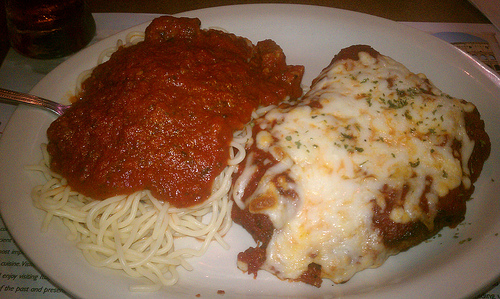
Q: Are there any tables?
A: Yes, there is a table.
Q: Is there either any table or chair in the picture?
A: Yes, there is a table.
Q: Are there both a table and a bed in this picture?
A: No, there is a table but no beds.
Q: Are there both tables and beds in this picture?
A: No, there is a table but no beds.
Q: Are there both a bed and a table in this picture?
A: No, there is a table but no beds.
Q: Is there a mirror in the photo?
A: No, there are no mirrors.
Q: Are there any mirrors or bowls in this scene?
A: No, there are no mirrors or bowls.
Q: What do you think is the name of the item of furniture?
A: The piece of furniture is a table.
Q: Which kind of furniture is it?
A: The piece of furniture is a table.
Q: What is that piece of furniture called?
A: This is a table.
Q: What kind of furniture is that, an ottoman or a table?
A: This is a table.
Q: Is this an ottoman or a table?
A: This is a table.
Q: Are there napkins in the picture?
A: No, there are no napkins.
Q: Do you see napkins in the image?
A: No, there are no napkins.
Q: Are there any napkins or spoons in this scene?
A: No, there are no napkins or spoons.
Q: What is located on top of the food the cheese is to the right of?
A: The sauce is on top of the noodles.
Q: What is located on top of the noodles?
A: The sauce is on top of the noodles.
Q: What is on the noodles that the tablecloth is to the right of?
A: The sauce is on the noodles.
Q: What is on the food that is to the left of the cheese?
A: The sauce is on the noodles.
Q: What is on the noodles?
A: The sauce is on the noodles.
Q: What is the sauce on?
A: The sauce is on the noodles.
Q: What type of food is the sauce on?
A: The sauce is on the noodles.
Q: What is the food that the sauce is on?
A: The food is noodles.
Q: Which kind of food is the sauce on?
A: The sauce is on the noodles.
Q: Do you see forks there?
A: Yes, there is a fork.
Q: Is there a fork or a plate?
A: Yes, there is a fork.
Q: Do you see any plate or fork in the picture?
A: Yes, there is a fork.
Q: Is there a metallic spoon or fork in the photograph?
A: Yes, there is a metal fork.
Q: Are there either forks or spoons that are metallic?
A: Yes, the fork is metallic.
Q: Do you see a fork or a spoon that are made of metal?
A: Yes, the fork is made of metal.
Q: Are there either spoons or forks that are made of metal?
A: Yes, the fork is made of metal.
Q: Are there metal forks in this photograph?
A: Yes, there is a metal fork.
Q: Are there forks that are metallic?
A: Yes, there is a fork that is metallic.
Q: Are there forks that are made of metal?
A: Yes, there is a fork that is made of metal.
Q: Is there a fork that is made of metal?
A: Yes, there is a fork that is made of metal.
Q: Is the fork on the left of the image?
A: Yes, the fork is on the left of the image.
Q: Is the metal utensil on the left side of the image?
A: Yes, the fork is on the left of the image.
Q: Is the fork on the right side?
A: No, the fork is on the left of the image.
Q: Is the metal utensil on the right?
A: No, the fork is on the left of the image.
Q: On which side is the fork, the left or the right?
A: The fork is on the left of the image.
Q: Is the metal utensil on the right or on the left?
A: The fork is on the left of the image.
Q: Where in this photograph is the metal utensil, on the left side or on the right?
A: The fork is on the left of the image.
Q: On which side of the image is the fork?
A: The fork is on the left of the image.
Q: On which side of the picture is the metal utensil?
A: The fork is on the left of the image.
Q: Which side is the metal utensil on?
A: The fork is on the left of the image.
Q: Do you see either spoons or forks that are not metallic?
A: No, there is a fork but it is metallic.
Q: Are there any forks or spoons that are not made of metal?
A: No, there is a fork but it is made of metal.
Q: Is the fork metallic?
A: Yes, the fork is metallic.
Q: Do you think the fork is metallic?
A: Yes, the fork is metallic.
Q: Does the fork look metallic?
A: Yes, the fork is metallic.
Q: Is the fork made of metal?
A: Yes, the fork is made of metal.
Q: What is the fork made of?
A: The fork is made of metal.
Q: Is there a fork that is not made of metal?
A: No, there is a fork but it is made of metal.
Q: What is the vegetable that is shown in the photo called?
A: The vegetable is a herb.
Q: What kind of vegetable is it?
A: The vegetable is a herb.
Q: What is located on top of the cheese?
A: The herb is on top of the cheese.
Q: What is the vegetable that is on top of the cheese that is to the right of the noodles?
A: The vegetable is a herb.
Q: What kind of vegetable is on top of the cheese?
A: The vegetable is a herb.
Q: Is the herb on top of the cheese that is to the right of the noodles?
A: Yes, the herb is on top of the cheese.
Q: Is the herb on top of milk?
A: No, the herb is on top of the cheese.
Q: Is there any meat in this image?
A: Yes, there is meat.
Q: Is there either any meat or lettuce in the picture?
A: Yes, there is meat.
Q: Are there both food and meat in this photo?
A: Yes, there are both meat and food.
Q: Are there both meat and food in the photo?
A: Yes, there are both meat and food.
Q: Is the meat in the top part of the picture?
A: Yes, the meat is in the top of the image.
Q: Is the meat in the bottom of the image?
A: No, the meat is in the top of the image.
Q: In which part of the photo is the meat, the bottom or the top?
A: The meat is in the top of the image.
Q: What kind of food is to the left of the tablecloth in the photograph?
A: The food is meat.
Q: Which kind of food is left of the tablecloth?
A: The food is meat.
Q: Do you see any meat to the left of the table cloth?
A: Yes, there is meat to the left of the table cloth.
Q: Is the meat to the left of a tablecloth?
A: Yes, the meat is to the left of a tablecloth.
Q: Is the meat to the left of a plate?
A: No, the meat is to the left of a tablecloth.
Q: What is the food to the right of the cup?
A: The food is meat.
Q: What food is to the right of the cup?
A: The food is meat.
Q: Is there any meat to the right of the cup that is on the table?
A: Yes, there is meat to the right of the cup.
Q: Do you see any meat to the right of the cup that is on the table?
A: Yes, there is meat to the right of the cup.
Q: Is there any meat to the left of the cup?
A: No, the meat is to the right of the cup.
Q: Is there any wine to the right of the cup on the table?
A: No, there is meat to the right of the cup.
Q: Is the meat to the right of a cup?
A: Yes, the meat is to the right of a cup.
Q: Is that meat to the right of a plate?
A: No, the meat is to the right of a cup.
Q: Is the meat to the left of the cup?
A: No, the meat is to the right of the cup.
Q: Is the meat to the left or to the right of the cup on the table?
A: The meat is to the right of the cup.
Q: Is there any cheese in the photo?
A: Yes, there is cheese.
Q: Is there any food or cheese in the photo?
A: Yes, there is cheese.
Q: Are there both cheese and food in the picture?
A: Yes, there are both cheese and food.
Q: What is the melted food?
A: The food is cheese.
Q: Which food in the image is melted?
A: The food is cheese.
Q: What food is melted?
A: The food is cheese.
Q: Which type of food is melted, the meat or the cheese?
A: The cheese is melted.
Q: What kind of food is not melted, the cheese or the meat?
A: The meat is not melted.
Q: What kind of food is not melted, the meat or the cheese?
A: The meat is not melted.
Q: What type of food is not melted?
A: The food is meat.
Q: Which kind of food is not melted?
A: The food is meat.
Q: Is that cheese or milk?
A: That is cheese.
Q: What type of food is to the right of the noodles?
A: The food is cheese.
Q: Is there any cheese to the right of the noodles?
A: Yes, there is cheese to the right of the noodles.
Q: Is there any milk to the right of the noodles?
A: No, there is cheese to the right of the noodles.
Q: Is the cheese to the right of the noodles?
A: Yes, the cheese is to the right of the noodles.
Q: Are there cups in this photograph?
A: Yes, there is a cup.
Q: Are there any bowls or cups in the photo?
A: Yes, there is a cup.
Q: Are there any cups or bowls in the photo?
A: Yes, there is a cup.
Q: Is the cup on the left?
A: Yes, the cup is on the left of the image.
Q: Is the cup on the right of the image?
A: No, the cup is on the left of the image.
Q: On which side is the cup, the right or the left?
A: The cup is on the left of the image.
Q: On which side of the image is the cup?
A: The cup is on the left of the image.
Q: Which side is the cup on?
A: The cup is on the left of the image.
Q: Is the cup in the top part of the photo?
A: Yes, the cup is in the top of the image.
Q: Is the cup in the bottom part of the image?
A: No, the cup is in the top of the image.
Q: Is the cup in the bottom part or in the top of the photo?
A: The cup is in the top of the image.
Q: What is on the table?
A: The cup is on the table.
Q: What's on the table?
A: The cup is on the table.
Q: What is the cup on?
A: The cup is on the table.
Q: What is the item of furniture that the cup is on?
A: The piece of furniture is a table.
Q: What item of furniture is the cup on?
A: The cup is on the table.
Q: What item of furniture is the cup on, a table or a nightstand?
A: The cup is on a table.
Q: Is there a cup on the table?
A: Yes, there is a cup on the table.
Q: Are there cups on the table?
A: Yes, there is a cup on the table.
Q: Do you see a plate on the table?
A: No, there is a cup on the table.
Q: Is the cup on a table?
A: Yes, the cup is on a table.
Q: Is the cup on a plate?
A: No, the cup is on a table.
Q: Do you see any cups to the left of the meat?
A: Yes, there is a cup to the left of the meat.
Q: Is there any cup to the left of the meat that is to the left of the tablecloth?
A: Yes, there is a cup to the left of the meat.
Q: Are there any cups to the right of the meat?
A: No, the cup is to the left of the meat.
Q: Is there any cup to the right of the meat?
A: No, the cup is to the left of the meat.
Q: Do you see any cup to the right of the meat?
A: No, the cup is to the left of the meat.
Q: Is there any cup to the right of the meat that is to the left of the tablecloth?
A: No, the cup is to the left of the meat.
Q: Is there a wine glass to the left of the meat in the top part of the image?
A: No, there is a cup to the left of the meat.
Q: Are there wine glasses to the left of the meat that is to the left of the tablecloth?
A: No, there is a cup to the left of the meat.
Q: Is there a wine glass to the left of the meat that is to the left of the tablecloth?
A: No, there is a cup to the left of the meat.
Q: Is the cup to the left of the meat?
A: Yes, the cup is to the left of the meat.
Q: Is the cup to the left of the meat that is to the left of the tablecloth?
A: Yes, the cup is to the left of the meat.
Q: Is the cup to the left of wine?
A: No, the cup is to the left of the meat.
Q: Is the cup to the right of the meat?
A: No, the cup is to the left of the meat.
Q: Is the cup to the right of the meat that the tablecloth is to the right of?
A: No, the cup is to the left of the meat.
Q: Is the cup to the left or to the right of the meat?
A: The cup is to the left of the meat.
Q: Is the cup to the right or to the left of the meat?
A: The cup is to the left of the meat.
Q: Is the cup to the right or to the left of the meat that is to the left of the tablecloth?
A: The cup is to the left of the meat.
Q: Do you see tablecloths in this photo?
A: Yes, there is a tablecloth.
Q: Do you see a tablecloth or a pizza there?
A: Yes, there is a tablecloth.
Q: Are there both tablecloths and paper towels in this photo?
A: No, there is a tablecloth but no paper towels.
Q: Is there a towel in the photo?
A: No, there are no towels.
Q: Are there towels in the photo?
A: No, there are no towels.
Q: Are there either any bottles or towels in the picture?
A: No, there are no towels or bottles.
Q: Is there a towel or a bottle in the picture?
A: No, there are no towels or bottles.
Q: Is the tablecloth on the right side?
A: Yes, the tablecloth is on the right of the image.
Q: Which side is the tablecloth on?
A: The tablecloth is on the right of the image.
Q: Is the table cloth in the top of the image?
A: Yes, the table cloth is in the top of the image.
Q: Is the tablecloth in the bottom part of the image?
A: No, the tablecloth is in the top of the image.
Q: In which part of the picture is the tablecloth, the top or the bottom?
A: The tablecloth is in the top of the image.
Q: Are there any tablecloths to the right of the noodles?
A: Yes, there is a tablecloth to the right of the noodles.